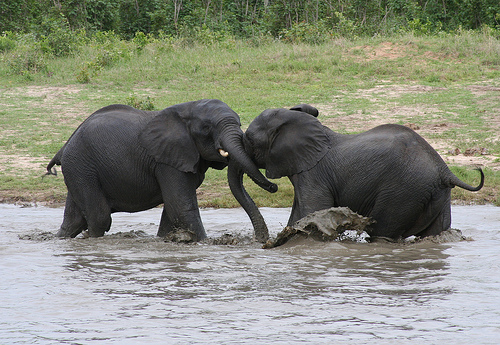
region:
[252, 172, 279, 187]
part of a trunk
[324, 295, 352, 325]
part of a water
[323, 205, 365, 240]
part of a splash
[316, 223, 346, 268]
part of a splash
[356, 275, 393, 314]
part of a wave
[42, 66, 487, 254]
two elephants playing in water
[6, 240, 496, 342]
water in a lake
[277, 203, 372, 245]
wave of splashing water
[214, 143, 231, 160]
tusks on an elephant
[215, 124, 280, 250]
intertwined trunks of two elephants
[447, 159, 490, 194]
an elephant's tail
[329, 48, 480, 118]
grass and dirt of land near water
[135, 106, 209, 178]
large elephant ear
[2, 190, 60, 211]
bank of a river that meets the land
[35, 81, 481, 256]
two young elephants playing in water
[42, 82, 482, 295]
elephants playing in the water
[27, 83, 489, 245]
the elephants are gray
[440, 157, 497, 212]
elephant's tail curled up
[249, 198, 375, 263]
water splashing the elephant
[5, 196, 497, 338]
the water is brown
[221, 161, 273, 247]
elephant's trunk touching water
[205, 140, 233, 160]
elephant's tusk is white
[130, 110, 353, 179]
elephant's ears touching their back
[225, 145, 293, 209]
elephant's trunk under other elephant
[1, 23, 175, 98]
weeds in the grass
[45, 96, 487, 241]
two elephants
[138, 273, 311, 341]
the water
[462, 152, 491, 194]
the elephants tail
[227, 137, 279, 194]
the elephant trunk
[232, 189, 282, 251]
the trunk of the elephant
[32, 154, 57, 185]
the elephants small tail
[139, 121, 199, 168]
the ear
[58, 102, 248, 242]
elephant is grey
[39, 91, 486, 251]
the elephants are standing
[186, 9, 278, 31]
the green bushes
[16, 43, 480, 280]
two elephants in the water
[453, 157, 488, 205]
tail of the elephant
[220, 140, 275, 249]
trunks of the elephant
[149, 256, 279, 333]
water next to the elephant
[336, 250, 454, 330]
reflection in the water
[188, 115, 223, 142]
eye of the elephant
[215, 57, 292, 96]
grass near the water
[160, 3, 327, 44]
trees behind the grass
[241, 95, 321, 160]
head of an elephant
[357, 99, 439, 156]
back of the elephant